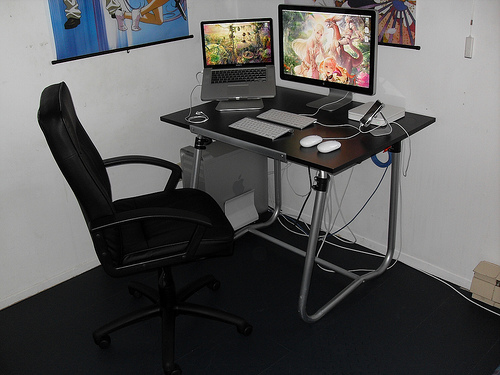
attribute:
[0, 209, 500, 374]
floor — dark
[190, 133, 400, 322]
legs — metal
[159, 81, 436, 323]
desk — black, grey, wooden, silver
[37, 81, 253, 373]
chair — black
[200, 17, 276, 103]
macbook — silver, open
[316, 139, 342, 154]
mouse — white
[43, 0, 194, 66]
poster — hanging, blue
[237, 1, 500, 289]
wall — white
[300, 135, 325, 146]
mouse — white